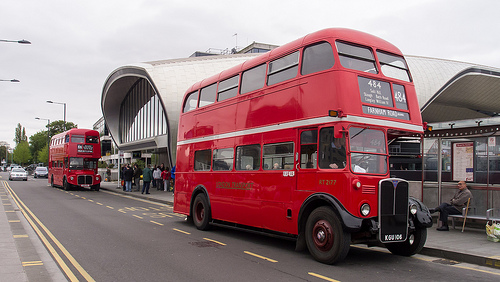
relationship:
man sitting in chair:
[426, 180, 471, 230] [448, 203, 498, 233]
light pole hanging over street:
[0, 78, 20, 83] [1, 165, 484, 279]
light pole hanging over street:
[1, 38, 30, 45] [1, 165, 484, 279]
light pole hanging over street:
[44, 99, 66, 130] [1, 165, 484, 279]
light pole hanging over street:
[32, 115, 51, 139] [1, 165, 484, 279]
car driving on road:
[9, 168, 30, 181] [2, 169, 498, 279]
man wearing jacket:
[136, 162, 153, 194] [139, 168, 155, 182]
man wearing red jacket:
[160, 166, 171, 195] [161, 170, 171, 178]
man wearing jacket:
[118, 160, 134, 192] [122, 168, 134, 182]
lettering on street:
[126, 195, 186, 223] [22, 172, 270, 279]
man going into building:
[160, 166, 171, 192] [93, 39, 496, 239]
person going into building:
[152, 166, 163, 191] [93, 39, 496, 239]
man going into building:
[140, 166, 153, 194] [93, 39, 496, 239]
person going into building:
[128, 165, 141, 189] [93, 39, 496, 239]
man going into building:
[123, 166, 134, 192] [93, 39, 496, 239]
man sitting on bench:
[426, 180, 471, 230] [421, 185, 499, 232]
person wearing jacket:
[151, 161, 161, 192] [151, 168, 161, 184]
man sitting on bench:
[427, 180, 474, 231] [421, 177, 499, 216]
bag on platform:
[486, 219, 498, 241] [422, 219, 498, 259]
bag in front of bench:
[486, 219, 498, 241] [437, 207, 498, 230]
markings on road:
[47, 178, 330, 279] [27, 187, 161, 266]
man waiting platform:
[140, 166, 153, 194] [101, 138, 172, 205]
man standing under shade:
[140, 166, 153, 194] [100, 61, 170, 145]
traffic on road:
[10, 129, 103, 186] [2, 179, 497, 280]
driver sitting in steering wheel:
[325, 138, 349, 166] [352, 153, 374, 164]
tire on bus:
[303, 202, 353, 262] [171, 25, 424, 260]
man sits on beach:
[427, 180, 474, 231] [449, 174, 478, 237]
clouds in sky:
[256, 0, 323, 33] [6, 2, 246, 95]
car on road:
[6, 156, 22, 181] [2, 177, 149, 267]